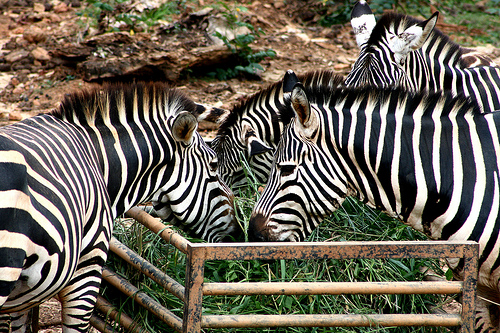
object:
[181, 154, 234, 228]
face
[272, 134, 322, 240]
face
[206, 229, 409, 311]
grass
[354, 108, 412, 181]
skin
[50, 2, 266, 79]
tree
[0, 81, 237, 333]
animal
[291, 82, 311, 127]
ear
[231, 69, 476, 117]
mane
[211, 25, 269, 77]
plants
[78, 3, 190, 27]
plants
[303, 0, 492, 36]
plants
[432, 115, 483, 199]
skin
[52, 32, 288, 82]
brown rock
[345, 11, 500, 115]
zebra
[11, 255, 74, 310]
stomach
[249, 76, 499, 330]
zebra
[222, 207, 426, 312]
plants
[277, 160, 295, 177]
eye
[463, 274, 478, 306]
marks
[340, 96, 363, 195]
stripe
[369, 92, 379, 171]
stripe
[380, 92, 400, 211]
stripe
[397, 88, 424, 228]
stripe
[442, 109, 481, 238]
stripe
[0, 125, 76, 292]
stripes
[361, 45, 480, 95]
stripes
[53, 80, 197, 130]
mane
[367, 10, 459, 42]
mane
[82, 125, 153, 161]
stripes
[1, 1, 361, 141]
ground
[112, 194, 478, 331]
trough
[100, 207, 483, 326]
fence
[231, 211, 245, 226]
nose